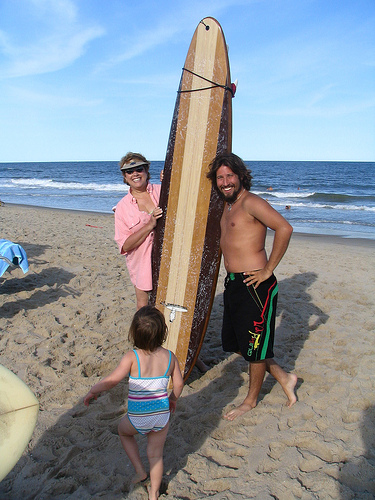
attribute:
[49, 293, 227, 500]
child — walking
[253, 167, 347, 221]
people — swimming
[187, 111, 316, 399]
man — smiling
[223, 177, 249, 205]
beard — brown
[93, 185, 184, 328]
shirt — peach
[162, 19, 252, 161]
surfboard — tan, brown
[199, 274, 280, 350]
swimsuit — yellow, blue, striped, polka dot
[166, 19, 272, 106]
board — surf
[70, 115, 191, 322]
woman — standing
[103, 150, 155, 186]
sunglass — black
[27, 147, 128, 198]
ocean — blue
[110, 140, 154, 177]
hat — visor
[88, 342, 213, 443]
suit — swim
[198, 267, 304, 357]
short — black